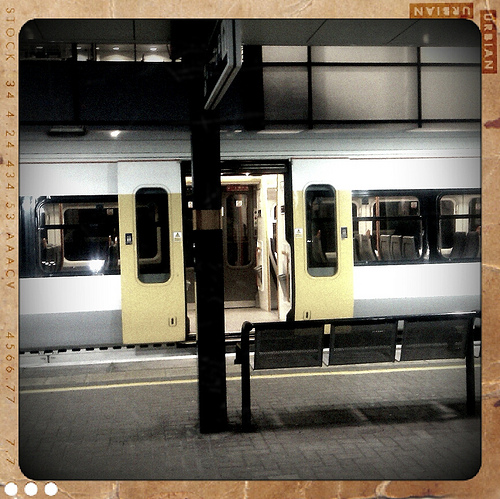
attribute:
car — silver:
[17, 120, 489, 361]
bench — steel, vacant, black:
[232, 309, 484, 431]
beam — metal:
[21, 349, 196, 364]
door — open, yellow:
[105, 155, 366, 352]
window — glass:
[353, 181, 485, 266]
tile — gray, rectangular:
[34, 355, 478, 486]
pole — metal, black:
[164, 46, 241, 443]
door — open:
[112, 156, 193, 355]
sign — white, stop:
[196, 19, 258, 123]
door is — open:
[287, 151, 364, 330]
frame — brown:
[245, 45, 486, 130]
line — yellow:
[36, 358, 475, 388]